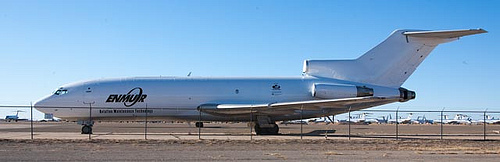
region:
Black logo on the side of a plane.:
[105, 91, 156, 116]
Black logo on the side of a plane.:
[77, 103, 92, 133]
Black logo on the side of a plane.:
[267, 76, 288, 101]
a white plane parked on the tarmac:
[33, 20, 468, 138]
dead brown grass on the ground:
[398, 138, 491, 160]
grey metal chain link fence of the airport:
[378, 108, 493, 143]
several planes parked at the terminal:
[326, 104, 491, 135]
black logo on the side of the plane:
[104, 85, 156, 107]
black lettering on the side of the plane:
[94, 105, 153, 114]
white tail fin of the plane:
[326, 25, 478, 87]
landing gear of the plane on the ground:
[72, 115, 296, 143]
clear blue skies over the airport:
[120, 8, 256, 64]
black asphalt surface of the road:
[86, 149, 228, 159]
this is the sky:
[189, 16, 233, 36]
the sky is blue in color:
[243, 15, 270, 31]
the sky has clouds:
[219, 40, 267, 77]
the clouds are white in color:
[201, 44, 236, 70]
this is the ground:
[179, 147, 211, 158]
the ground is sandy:
[175, 134, 223, 158]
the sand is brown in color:
[199, 135, 241, 158]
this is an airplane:
[45, 22, 483, 133]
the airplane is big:
[31, 21, 487, 133]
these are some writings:
[101, 83, 156, 105]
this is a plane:
[25, 4, 475, 135]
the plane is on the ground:
[20, 20, 470, 135]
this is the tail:
[341, 22, 491, 84]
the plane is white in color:
[195, 78, 236, 99]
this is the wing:
[268, 87, 368, 123]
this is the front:
[34, 90, 59, 110]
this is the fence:
[146, 102, 176, 137]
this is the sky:
[188, 6, 269, 51]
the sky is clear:
[180, 2, 248, 52]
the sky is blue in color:
[168, 0, 227, 45]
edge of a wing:
[388, 47, 406, 75]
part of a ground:
[255, 143, 268, 155]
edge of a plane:
[251, 65, 269, 75]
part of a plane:
[237, 84, 254, 104]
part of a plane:
[329, 55, 362, 87]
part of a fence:
[232, 94, 255, 114]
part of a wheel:
[260, 119, 273, 131]